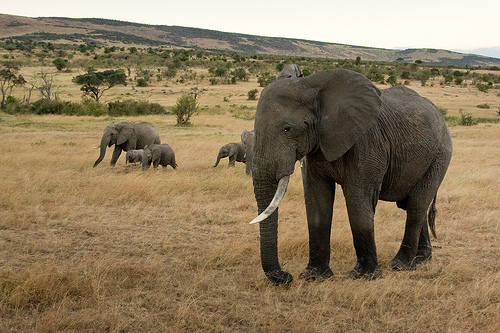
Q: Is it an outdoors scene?
A: Yes, it is outdoors.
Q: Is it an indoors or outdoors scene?
A: It is outdoors.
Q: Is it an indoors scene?
A: No, it is outdoors.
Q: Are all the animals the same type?
A: Yes, all the animals are elephants.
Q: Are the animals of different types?
A: No, all the animals are elephants.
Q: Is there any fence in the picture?
A: No, there are no fences.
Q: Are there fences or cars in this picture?
A: No, there are no fences or cars.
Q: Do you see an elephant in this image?
A: Yes, there is an elephant.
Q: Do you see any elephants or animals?
A: Yes, there is an elephant.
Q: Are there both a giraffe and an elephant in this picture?
A: No, there is an elephant but no giraffes.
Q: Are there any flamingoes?
A: No, there are no flamingoes.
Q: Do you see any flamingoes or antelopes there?
A: No, there are no flamingoes or antelopes.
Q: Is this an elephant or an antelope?
A: This is an elephant.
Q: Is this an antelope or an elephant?
A: This is an elephant.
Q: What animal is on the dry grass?
A: The animal is an elephant.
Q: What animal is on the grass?
A: The animal is an elephant.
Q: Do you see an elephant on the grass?
A: Yes, there is an elephant on the grass.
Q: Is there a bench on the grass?
A: No, there is an elephant on the grass.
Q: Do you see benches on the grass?
A: No, there is an elephant on the grass.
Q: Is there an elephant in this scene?
A: Yes, there is an elephant.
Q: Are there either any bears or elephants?
A: Yes, there is an elephant.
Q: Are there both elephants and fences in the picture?
A: No, there is an elephant but no fences.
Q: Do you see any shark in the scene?
A: No, there are no sharks.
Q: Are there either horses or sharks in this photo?
A: No, there are no sharks or horses.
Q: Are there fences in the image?
A: No, there are no fences.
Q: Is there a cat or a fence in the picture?
A: No, there are no fences or cats.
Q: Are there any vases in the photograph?
A: No, there are no vases.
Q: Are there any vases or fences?
A: No, there are no vases or fences.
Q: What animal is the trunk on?
A: The trunk is on the elephant.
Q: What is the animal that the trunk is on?
A: The animal is an elephant.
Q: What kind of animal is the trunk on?
A: The trunk is on the elephant.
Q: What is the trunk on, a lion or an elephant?
A: The trunk is on an elephant.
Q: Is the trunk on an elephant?
A: Yes, the trunk is on an elephant.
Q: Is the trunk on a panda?
A: No, the trunk is on an elephant.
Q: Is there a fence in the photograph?
A: No, there are no fences.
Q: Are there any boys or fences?
A: No, there are no fences or boys.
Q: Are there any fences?
A: No, there are no fences.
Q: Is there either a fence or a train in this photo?
A: No, there are no fences or trains.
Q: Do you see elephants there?
A: Yes, there are elephants.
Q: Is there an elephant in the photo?
A: Yes, there are elephants.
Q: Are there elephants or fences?
A: Yes, there are elephants.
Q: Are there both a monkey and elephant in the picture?
A: No, there are elephants but no monkeys.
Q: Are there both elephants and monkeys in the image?
A: No, there are elephants but no monkeys.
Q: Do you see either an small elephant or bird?
A: Yes, there are small elephants.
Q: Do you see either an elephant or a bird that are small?
A: Yes, the elephants are small.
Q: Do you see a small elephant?
A: Yes, there are small elephants.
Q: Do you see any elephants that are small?
A: Yes, there are small elephants.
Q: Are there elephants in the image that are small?
A: Yes, there are elephants that are small.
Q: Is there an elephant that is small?
A: Yes, there are elephants that are small.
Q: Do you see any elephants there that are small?
A: Yes, there are elephants that are small.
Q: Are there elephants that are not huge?
A: Yes, there are small elephants.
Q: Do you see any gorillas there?
A: No, there are no gorillas.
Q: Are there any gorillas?
A: No, there are no gorillas.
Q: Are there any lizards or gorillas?
A: No, there are no gorillas or lizards.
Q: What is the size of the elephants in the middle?
A: The elephants are small.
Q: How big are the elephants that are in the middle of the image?
A: The elephants are small.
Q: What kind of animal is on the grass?
A: The animals are elephants.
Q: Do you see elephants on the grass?
A: Yes, there are elephants on the grass.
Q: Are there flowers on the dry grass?
A: No, there are elephants on the grass.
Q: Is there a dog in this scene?
A: No, there are no dogs.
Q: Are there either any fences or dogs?
A: No, there are no dogs or fences.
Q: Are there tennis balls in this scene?
A: No, there are no tennis balls.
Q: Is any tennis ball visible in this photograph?
A: No, there are no tennis balls.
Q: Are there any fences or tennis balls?
A: No, there are no tennis balls or fences.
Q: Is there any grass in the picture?
A: Yes, there is grass.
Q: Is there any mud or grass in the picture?
A: Yes, there is grass.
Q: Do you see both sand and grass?
A: No, there is grass but no sand.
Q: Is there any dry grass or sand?
A: Yes, there is dry grass.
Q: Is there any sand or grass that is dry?
A: Yes, the grass is dry.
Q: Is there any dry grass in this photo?
A: Yes, there is dry grass.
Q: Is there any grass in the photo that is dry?
A: Yes, there is grass that is dry.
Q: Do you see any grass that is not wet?
A: Yes, there is dry grass.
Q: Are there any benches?
A: No, there are no benches.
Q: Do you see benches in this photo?
A: No, there are no benches.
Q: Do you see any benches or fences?
A: No, there are no benches or fences.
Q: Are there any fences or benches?
A: No, there are no benches or fences.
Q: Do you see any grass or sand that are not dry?
A: No, there is grass but it is dry.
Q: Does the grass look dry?
A: Yes, the grass is dry.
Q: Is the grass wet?
A: No, the grass is dry.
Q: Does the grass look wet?
A: No, the grass is dry.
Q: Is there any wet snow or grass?
A: No, there is grass but it is dry.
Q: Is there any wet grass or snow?
A: No, there is grass but it is dry.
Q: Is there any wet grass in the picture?
A: No, there is grass but it is dry.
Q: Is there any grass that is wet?
A: No, there is grass but it is dry.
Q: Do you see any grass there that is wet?
A: No, there is grass but it is dry.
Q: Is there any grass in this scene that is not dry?
A: No, there is grass but it is dry.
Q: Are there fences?
A: No, there are no fences.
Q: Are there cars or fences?
A: No, there are no fences or cars.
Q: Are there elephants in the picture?
A: Yes, there is an elephant.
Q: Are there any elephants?
A: Yes, there is an elephant.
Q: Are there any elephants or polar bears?
A: Yes, there is an elephant.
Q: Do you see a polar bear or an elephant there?
A: Yes, there is an elephant.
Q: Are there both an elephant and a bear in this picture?
A: No, there is an elephant but no bears.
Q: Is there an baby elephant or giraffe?
A: Yes, there is a baby elephant.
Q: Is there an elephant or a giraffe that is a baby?
A: Yes, the elephant is a baby.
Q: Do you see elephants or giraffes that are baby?
A: Yes, the elephant is a baby.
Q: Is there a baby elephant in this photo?
A: Yes, there is a baby elephant.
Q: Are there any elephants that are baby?
A: Yes, there is an elephant that is a baby.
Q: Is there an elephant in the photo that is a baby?
A: Yes, there is an elephant that is a baby.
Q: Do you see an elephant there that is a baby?
A: Yes, there is an elephant that is a baby.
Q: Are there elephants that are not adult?
A: Yes, there is an baby elephant.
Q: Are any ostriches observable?
A: No, there are no ostriches.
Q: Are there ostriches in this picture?
A: No, there are no ostriches.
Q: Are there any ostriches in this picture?
A: No, there are no ostriches.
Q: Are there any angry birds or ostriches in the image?
A: No, there are no ostriches or angry birds.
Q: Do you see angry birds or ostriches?
A: No, there are no ostriches or angry birds.